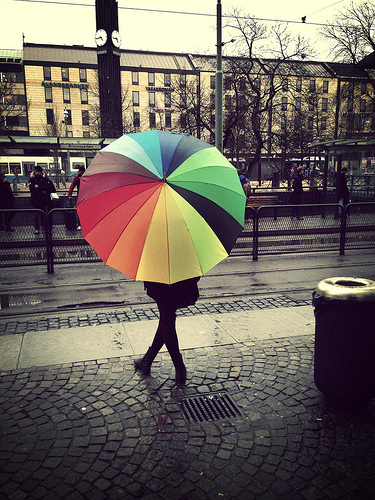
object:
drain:
[175, 393, 246, 422]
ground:
[116, 380, 319, 500]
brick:
[239, 377, 254, 388]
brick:
[275, 357, 288, 367]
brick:
[300, 352, 313, 361]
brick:
[94, 356, 109, 365]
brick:
[113, 390, 130, 402]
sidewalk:
[1, 207, 373, 496]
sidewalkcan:
[311, 276, 372, 407]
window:
[45, 87, 51, 103]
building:
[0, 31, 375, 153]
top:
[314, 274, 374, 299]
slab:
[0, 305, 314, 375]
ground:
[255, 124, 268, 147]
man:
[26, 165, 57, 234]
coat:
[28, 176, 57, 207]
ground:
[280, 121, 344, 160]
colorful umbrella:
[74, 129, 249, 288]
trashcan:
[311, 275, 374, 402]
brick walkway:
[0, 290, 374, 498]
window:
[44, 67, 51, 81]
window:
[47, 109, 54, 125]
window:
[81, 88, 88, 104]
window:
[63, 88, 70, 103]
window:
[80, 69, 87, 83]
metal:
[0, 204, 370, 275]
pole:
[215, 1, 224, 154]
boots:
[174, 363, 186, 382]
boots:
[134, 345, 157, 374]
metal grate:
[178, 391, 246, 424]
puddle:
[11, 293, 42, 305]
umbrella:
[73, 128, 247, 284]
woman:
[134, 276, 201, 384]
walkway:
[5, 292, 370, 498]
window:
[132, 72, 138, 85]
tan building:
[16, 32, 373, 156]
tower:
[92, 2, 123, 140]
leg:
[142, 323, 165, 362]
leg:
[161, 310, 180, 366]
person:
[27, 166, 57, 235]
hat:
[34, 165, 43, 170]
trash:
[310, 277, 373, 403]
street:
[0, 241, 375, 500]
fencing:
[0, 202, 368, 276]